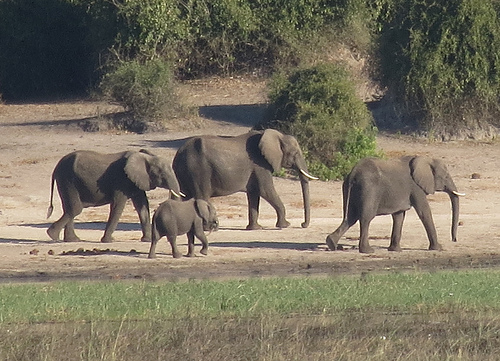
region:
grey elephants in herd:
[42, 126, 466, 258]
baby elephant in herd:
[150, 195, 222, 259]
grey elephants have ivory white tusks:
[45, 128, 465, 251]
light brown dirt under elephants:
[1, 73, 499, 277]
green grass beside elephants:
[0, 260, 499, 323]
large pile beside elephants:
[28, 245, 138, 259]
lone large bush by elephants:
[261, 59, 383, 181]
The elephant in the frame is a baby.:
[146, 197, 218, 257]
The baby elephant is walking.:
[143, 201, 226, 261]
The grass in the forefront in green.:
[185, 287, 299, 314]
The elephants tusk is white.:
[451, 187, 467, 199]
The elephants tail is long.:
[46, 172, 55, 222]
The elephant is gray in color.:
[42, 148, 186, 245]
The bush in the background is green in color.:
[268, 64, 375, 179]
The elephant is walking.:
[324, 155, 466, 255]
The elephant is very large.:
[174, 127, 316, 229]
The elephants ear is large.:
[257, 128, 282, 178]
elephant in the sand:
[321, 151, 478, 271]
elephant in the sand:
[177, 126, 319, 187]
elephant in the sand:
[155, 190, 235, 245]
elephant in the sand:
[45, 135, 151, 240]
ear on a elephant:
[120, 145, 155, 190]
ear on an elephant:
[250, 125, 285, 167]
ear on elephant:
[405, 150, 435, 197]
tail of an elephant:
[340, 172, 355, 224]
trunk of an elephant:
[441, 193, 466, 243]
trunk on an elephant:
[292, 174, 316, 238]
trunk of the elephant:
[423, 181, 478, 263]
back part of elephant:
[308, 143, 393, 258]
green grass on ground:
[314, 271, 415, 318]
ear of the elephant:
[244, 120, 299, 186]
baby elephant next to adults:
[128, 191, 227, 268]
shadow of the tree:
[186, 80, 257, 137]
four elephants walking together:
[36, 114, 466, 254]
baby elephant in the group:
[145, 200, 218, 254]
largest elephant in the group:
[178, 124, 316, 231]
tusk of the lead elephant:
[448, 184, 468, 198]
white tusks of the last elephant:
[165, 189, 189, 198]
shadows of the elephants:
[7, 207, 349, 267]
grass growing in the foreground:
[12, 277, 498, 359]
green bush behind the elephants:
[267, 62, 373, 175]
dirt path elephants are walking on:
[6, 89, 498, 260]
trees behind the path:
[14, 5, 499, 105]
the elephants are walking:
[33, 105, 487, 287]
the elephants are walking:
[32, 102, 459, 268]